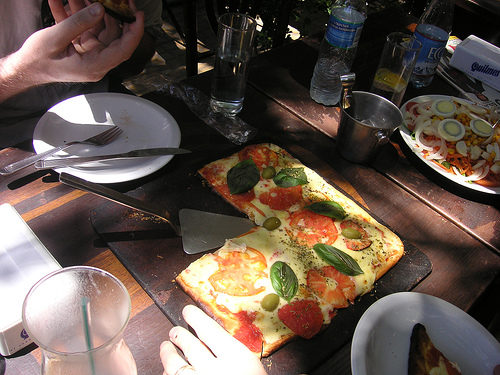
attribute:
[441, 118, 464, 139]
egg — hard boiled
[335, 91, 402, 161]
bucket — metal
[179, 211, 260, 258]
spatula — silver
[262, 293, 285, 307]
olive — olive colored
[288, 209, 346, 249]
tomato — red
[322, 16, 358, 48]
label — blue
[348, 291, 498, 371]
plate — white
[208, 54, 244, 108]
liquid — clear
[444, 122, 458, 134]
yoke — yellow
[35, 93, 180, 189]
plate — white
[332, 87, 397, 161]
cup — metal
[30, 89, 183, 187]
plate — small, white, round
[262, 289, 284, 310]
olive — green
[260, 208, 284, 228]
olive — green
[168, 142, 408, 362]
pizza — square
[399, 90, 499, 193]
plate — white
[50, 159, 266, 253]
spatula — large 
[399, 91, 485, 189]
salad — large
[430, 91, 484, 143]
eggs — boiled 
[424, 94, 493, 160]
eggs — BOILED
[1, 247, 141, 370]
glass — hurricane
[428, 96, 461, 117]
egg — boiled, halved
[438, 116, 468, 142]
egg — boiled, halved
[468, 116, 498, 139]
egg — boiled, halved